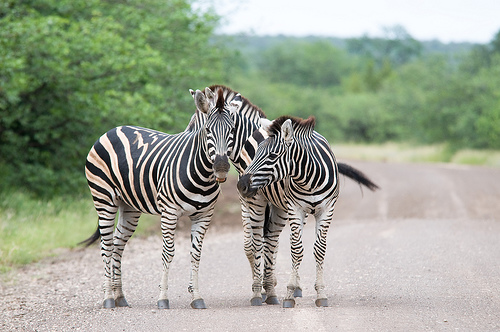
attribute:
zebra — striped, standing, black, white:
[76, 89, 241, 310]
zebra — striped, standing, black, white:
[187, 84, 376, 303]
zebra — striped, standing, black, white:
[236, 115, 339, 307]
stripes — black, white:
[105, 127, 144, 208]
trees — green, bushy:
[1, 0, 255, 203]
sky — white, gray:
[186, 3, 498, 47]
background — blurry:
[34, 1, 481, 136]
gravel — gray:
[5, 278, 93, 330]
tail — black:
[333, 157, 379, 195]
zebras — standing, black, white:
[73, 84, 380, 311]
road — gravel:
[2, 135, 495, 331]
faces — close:
[203, 109, 293, 197]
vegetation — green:
[183, 44, 495, 143]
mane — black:
[268, 117, 316, 134]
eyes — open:
[205, 128, 238, 137]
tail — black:
[76, 219, 103, 254]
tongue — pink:
[215, 176, 227, 182]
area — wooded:
[192, 35, 486, 114]